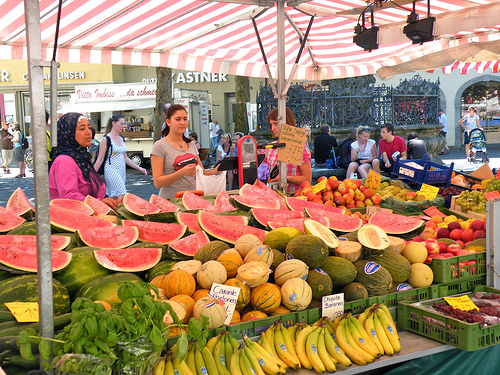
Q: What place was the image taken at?
A: It was taken at the town.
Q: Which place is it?
A: It is a town.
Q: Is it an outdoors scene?
A: Yes, it is outdoors.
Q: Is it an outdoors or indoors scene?
A: It is outdoors.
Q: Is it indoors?
A: No, it is outdoors.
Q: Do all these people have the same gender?
A: No, they are both male and female.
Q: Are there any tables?
A: Yes, there is a table.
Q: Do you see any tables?
A: Yes, there is a table.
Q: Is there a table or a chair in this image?
A: Yes, there is a table.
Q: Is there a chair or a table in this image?
A: Yes, there is a table.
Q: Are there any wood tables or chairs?
A: Yes, there is a wood table.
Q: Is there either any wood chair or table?
A: Yes, there is a wood table.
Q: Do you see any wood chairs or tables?
A: Yes, there is a wood table.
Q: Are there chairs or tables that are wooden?
A: Yes, the table is wooden.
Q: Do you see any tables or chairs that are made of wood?
A: Yes, the table is made of wood.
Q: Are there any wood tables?
A: Yes, there is a wood table.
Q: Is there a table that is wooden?
A: Yes, there is a table that is wooden.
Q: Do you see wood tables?
A: Yes, there is a table that is made of wood.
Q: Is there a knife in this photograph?
A: No, there are no knives.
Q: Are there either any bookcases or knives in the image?
A: No, there are no knives or bookcases.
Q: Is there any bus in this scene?
A: No, there are no buses.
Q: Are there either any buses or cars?
A: No, there are no buses or cars.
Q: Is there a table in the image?
A: Yes, there is a table.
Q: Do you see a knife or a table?
A: Yes, there is a table.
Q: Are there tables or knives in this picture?
A: Yes, there is a table.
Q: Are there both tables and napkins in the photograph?
A: No, there is a table but no napkins.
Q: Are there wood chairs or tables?
A: Yes, there is a wood table.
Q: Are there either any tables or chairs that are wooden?
A: Yes, the table is wooden.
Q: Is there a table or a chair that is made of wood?
A: Yes, the table is made of wood.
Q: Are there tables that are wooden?
A: Yes, there is a table that is wooden.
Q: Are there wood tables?
A: Yes, there is a table that is made of wood.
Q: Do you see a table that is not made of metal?
A: Yes, there is a table that is made of wood.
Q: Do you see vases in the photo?
A: No, there are no vases.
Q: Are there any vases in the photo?
A: No, there are no vases.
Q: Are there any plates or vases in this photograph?
A: No, there are no vases or plates.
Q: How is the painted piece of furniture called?
A: The piece of furniture is a table.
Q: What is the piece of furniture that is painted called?
A: The piece of furniture is a table.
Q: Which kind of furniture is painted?
A: The furniture is a table.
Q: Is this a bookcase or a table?
A: This is a table.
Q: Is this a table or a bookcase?
A: This is a table.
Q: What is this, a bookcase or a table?
A: This is a table.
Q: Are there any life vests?
A: No, there are no life vests.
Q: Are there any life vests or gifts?
A: No, there are no life vests or gifts.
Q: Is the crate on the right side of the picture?
A: Yes, the crate is on the right of the image.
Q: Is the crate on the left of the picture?
A: No, the crate is on the right of the image.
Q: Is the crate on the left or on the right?
A: The crate is on the right of the image.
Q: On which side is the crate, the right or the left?
A: The crate is on the right of the image.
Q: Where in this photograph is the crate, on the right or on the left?
A: The crate is on the right of the image.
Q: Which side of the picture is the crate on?
A: The crate is on the right of the image.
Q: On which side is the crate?
A: The crate is on the right of the image.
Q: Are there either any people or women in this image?
A: Yes, there is a woman.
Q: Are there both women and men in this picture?
A: Yes, there are both a woman and a man.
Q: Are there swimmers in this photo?
A: No, there are no swimmers.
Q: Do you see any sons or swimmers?
A: No, there are no swimmers or sons.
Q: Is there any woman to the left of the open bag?
A: Yes, there is a woman to the left of the bag.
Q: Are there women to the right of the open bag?
A: No, the woman is to the left of the bag.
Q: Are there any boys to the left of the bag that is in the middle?
A: No, there is a woman to the left of the bag.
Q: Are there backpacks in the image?
A: Yes, there is a backpack.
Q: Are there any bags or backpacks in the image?
A: Yes, there is a backpack.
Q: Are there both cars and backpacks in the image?
A: No, there is a backpack but no cars.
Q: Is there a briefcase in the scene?
A: No, there are no briefcases.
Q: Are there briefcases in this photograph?
A: No, there are no briefcases.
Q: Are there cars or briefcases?
A: No, there are no briefcases or cars.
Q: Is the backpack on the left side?
A: Yes, the backpack is on the left of the image.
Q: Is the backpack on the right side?
A: No, the backpack is on the left of the image.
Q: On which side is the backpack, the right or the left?
A: The backpack is on the left of the image.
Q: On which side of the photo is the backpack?
A: The backpack is on the left of the image.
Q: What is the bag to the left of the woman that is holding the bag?
A: The bag is a backpack.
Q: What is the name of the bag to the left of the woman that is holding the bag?
A: The bag is a backpack.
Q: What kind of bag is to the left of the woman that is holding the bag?
A: The bag is a backpack.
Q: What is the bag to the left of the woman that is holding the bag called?
A: The bag is a backpack.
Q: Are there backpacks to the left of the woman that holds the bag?
A: Yes, there is a backpack to the left of the woman.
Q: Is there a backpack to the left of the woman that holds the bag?
A: Yes, there is a backpack to the left of the woman.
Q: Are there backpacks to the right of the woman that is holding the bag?
A: No, the backpack is to the left of the woman.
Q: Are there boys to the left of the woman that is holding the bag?
A: No, there is a backpack to the left of the woman.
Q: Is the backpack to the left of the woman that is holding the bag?
A: Yes, the backpack is to the left of the woman.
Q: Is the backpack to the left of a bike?
A: No, the backpack is to the left of the woman.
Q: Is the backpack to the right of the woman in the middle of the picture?
A: No, the backpack is to the left of the woman.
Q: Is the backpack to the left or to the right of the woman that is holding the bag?
A: The backpack is to the left of the woman.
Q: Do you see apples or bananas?
A: Yes, there are bananas.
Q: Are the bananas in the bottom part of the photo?
A: Yes, the bananas are in the bottom of the image.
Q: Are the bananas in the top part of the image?
A: No, the bananas are in the bottom of the image.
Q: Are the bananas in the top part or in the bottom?
A: The bananas are in the bottom of the image.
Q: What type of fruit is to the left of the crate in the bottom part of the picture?
A: The fruits are bananas.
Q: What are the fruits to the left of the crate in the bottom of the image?
A: The fruits are bananas.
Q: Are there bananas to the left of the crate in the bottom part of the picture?
A: Yes, there are bananas to the left of the crate.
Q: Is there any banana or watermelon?
A: Yes, there is a watermelon.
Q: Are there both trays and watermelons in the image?
A: No, there is a watermelon but no trays.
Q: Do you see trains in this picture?
A: Yes, there is a train.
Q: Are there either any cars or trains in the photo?
A: Yes, there is a train.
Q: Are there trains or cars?
A: Yes, there is a train.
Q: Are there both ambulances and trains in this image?
A: No, there is a train but no ambulances.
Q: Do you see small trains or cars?
A: Yes, there is a small train.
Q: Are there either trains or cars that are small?
A: Yes, the train is small.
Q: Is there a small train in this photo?
A: Yes, there is a small train.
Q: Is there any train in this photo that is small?
A: Yes, there is a train that is small.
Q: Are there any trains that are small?
A: Yes, there is a train that is small.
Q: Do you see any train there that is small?
A: Yes, there is a train that is small.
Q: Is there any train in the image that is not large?
A: Yes, there is a small train.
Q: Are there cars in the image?
A: No, there are no cars.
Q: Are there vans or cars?
A: No, there are no cars or vans.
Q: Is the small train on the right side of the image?
A: Yes, the train is on the right of the image.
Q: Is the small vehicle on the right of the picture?
A: Yes, the train is on the right of the image.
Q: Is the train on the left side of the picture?
A: No, the train is on the right of the image.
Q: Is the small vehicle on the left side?
A: No, the train is on the right of the image.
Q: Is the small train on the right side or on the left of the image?
A: The train is on the right of the image.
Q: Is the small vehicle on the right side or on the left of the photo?
A: The train is on the right of the image.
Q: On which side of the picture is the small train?
A: The train is on the right of the image.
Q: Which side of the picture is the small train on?
A: The train is on the right of the image.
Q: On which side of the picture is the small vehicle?
A: The train is on the right of the image.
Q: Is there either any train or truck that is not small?
A: No, there is a train but it is small.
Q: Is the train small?
A: Yes, the train is small.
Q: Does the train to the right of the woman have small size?
A: Yes, the train is small.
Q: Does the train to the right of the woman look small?
A: Yes, the train is small.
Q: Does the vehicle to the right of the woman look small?
A: Yes, the train is small.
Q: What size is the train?
A: The train is small.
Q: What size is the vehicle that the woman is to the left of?
A: The train is small.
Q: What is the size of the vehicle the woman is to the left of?
A: The train is small.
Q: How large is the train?
A: The train is small.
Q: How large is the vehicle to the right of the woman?
A: The train is small.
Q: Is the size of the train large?
A: No, the train is small.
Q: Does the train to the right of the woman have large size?
A: No, the train is small.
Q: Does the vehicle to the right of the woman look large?
A: No, the train is small.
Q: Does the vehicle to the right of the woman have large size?
A: No, the train is small.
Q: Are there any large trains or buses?
A: No, there is a train but it is small.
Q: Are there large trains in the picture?
A: No, there is a train but it is small.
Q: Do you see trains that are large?
A: No, there is a train but it is small.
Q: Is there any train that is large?
A: No, there is a train but it is small.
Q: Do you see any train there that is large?
A: No, there is a train but it is small.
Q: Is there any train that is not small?
A: No, there is a train but it is small.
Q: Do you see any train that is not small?
A: No, there is a train but it is small.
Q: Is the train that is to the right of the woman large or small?
A: The train is small.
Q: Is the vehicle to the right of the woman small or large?
A: The train is small.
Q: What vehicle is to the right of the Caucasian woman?
A: The vehicle is a train.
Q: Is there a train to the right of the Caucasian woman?
A: Yes, there is a train to the right of the woman.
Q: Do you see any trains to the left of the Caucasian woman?
A: No, the train is to the right of the woman.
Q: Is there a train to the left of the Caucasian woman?
A: No, the train is to the right of the woman.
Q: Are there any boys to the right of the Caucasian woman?
A: No, there is a train to the right of the woman.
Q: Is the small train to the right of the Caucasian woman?
A: Yes, the train is to the right of the woman.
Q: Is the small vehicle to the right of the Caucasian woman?
A: Yes, the train is to the right of the woman.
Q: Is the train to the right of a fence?
A: No, the train is to the right of the woman.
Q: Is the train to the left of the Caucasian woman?
A: No, the train is to the right of the woman.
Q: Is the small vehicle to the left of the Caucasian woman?
A: No, the train is to the right of the woman.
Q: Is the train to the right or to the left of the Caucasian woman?
A: The train is to the right of the woman.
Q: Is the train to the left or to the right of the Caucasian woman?
A: The train is to the right of the woman.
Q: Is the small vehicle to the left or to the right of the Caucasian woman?
A: The train is to the right of the woman.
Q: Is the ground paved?
A: Yes, the ground is paved.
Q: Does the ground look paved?
A: Yes, the ground is paved.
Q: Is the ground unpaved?
A: No, the ground is paved.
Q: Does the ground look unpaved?
A: No, the ground is paved.